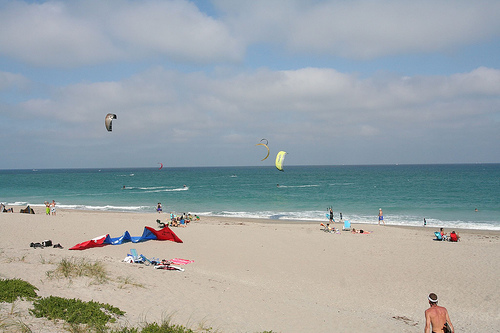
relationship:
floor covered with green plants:
[3, 208, 499, 332] [28, 296, 120, 323]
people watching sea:
[433, 227, 462, 243] [310, 169, 486, 199]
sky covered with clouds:
[3, 3, 499, 168] [6, 4, 496, 65]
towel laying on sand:
[168, 256, 193, 267] [117, 242, 225, 289]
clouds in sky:
[0, 0, 498, 166] [3, 3, 499, 168]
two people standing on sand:
[40, 199, 60, 215] [0, 203, 498, 331]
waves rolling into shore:
[4, 193, 158, 214] [0, 186, 496, 246]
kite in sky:
[269, 146, 293, 170] [3, 3, 499, 168]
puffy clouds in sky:
[255, 69, 366, 127] [3, 3, 499, 168]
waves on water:
[131, 175, 192, 205] [187, 143, 261, 188]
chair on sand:
[125, 247, 153, 263] [0, 203, 498, 331]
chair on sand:
[158, 256, 195, 267] [0, 203, 498, 331]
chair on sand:
[341, 220, 351, 230] [0, 203, 498, 331]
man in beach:
[417, 292, 458, 333] [0, 191, 498, 331]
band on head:
[424, 295, 440, 302] [426, 290, 439, 305]